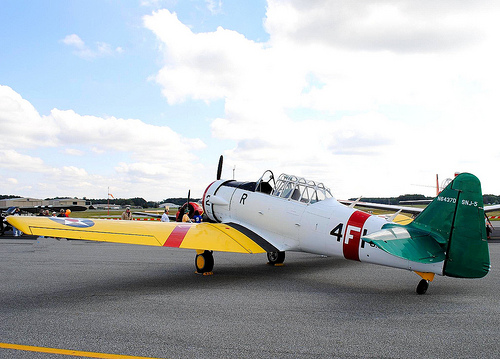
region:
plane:
[30, 178, 440, 315]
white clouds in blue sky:
[368, 25, 425, 66]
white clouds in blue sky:
[322, 118, 370, 135]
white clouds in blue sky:
[341, 18, 383, 82]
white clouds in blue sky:
[18, 56, 110, 106]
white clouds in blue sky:
[115, 52, 163, 97]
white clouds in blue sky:
[221, 49, 286, 101]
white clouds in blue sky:
[55, 26, 119, 101]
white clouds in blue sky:
[74, 56, 129, 150]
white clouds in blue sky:
[295, 69, 355, 131]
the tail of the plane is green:
[371, 142, 488, 308]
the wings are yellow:
[1, 192, 270, 284]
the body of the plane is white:
[183, 131, 447, 301]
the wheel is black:
[173, 244, 222, 289]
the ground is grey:
[37, 273, 300, 334]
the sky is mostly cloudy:
[149, 2, 476, 153]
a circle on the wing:
[40, 212, 108, 234]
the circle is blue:
[45, 204, 93, 237]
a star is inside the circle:
[50, 209, 90, 227]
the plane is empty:
[233, 167, 322, 208]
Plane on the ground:
[6, 154, 491, 294]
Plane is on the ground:
[4, 151, 496, 297]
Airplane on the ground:
[0, 150, 492, 295]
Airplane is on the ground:
[0, 151, 495, 297]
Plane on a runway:
[2, 153, 491, 297]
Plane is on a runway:
[0, 147, 496, 293]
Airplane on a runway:
[5, 148, 491, 300]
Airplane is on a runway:
[0, 150, 494, 295]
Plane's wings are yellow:
[3, 200, 428, 258]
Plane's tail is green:
[372, 172, 494, 279]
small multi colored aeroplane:
[0, 145, 494, 300]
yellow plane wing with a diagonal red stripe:
[4, 208, 274, 259]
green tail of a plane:
[353, 169, 491, 282]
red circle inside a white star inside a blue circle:
[47, 213, 94, 229]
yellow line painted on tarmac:
[0, 335, 165, 357]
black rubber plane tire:
[192, 248, 213, 275]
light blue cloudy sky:
[0, 0, 499, 207]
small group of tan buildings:
[0, 195, 87, 211]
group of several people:
[2, 206, 203, 224]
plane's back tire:
[405, 268, 435, 300]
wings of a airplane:
[6, 193, 271, 275]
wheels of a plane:
[192, 248, 224, 275]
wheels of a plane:
[408, 272, 433, 292]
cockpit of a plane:
[205, 165, 337, 250]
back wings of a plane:
[367, 148, 497, 286]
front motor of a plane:
[164, 156, 239, 218]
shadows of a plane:
[40, 274, 201, 325]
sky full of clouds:
[126, 15, 438, 128]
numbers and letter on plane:
[327, 200, 367, 253]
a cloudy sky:
[22, 105, 190, 162]